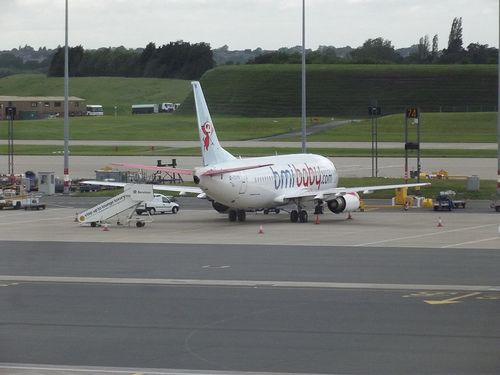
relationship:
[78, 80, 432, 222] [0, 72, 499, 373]
airplane on ground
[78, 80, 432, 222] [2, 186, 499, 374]
airplane on ground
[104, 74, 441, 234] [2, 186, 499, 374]
airplane on ground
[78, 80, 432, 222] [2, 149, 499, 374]
airplane on ground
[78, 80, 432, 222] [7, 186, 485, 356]
airplane on ground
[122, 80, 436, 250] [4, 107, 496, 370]
airplane on ground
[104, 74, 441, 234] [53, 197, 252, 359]
airplane on ground